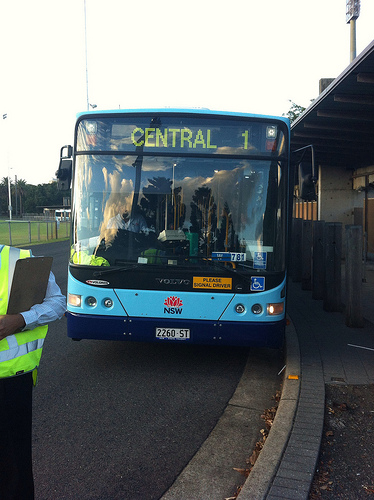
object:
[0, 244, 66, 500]
man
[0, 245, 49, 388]
green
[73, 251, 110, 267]
vest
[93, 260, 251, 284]
dash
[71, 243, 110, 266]
green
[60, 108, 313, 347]
bus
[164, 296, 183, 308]
flower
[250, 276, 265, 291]
sign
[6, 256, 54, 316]
clipbaord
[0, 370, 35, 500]
pants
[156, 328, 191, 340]
license plate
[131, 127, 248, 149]
marquee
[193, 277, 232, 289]
sticker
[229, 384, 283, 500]
leaves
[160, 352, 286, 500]
gutter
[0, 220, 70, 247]
field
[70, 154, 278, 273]
window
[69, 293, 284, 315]
lights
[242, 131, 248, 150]
number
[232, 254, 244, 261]
781